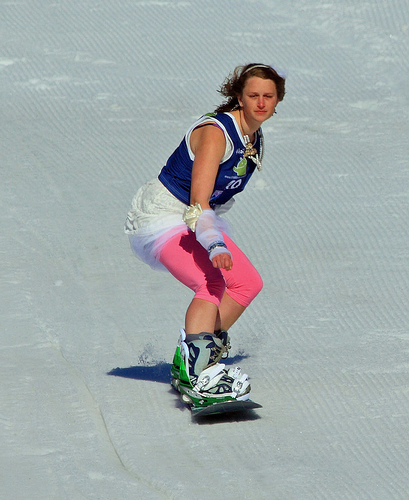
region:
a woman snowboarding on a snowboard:
[124, 61, 287, 416]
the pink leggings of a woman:
[156, 222, 263, 303]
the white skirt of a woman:
[127, 182, 235, 258]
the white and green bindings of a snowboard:
[175, 345, 248, 406]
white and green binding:
[172, 328, 198, 385]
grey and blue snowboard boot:
[187, 335, 249, 398]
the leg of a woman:
[152, 225, 219, 359]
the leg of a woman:
[195, 206, 258, 342]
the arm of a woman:
[190, 118, 222, 249]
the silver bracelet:
[207, 241, 225, 252]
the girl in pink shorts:
[87, 189, 278, 381]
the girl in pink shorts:
[100, 80, 348, 425]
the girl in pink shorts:
[116, 85, 250, 341]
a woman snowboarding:
[96, 69, 332, 433]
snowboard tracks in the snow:
[278, 343, 382, 499]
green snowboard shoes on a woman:
[166, 349, 229, 415]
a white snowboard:
[170, 376, 261, 432]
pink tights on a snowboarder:
[150, 225, 304, 341]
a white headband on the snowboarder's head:
[237, 65, 280, 80]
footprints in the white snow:
[277, 28, 394, 153]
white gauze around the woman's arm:
[189, 202, 228, 266]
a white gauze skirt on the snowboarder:
[117, 197, 215, 246]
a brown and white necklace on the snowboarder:
[233, 120, 268, 181]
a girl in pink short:
[82, 149, 323, 390]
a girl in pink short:
[98, 81, 245, 304]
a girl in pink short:
[141, 80, 330, 326]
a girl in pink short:
[152, 144, 285, 294]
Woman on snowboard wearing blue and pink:
[106, 43, 319, 439]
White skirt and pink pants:
[127, 182, 266, 339]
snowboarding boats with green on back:
[170, 331, 262, 419]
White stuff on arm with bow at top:
[174, 200, 236, 278]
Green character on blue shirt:
[231, 150, 250, 178]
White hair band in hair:
[236, 60, 272, 79]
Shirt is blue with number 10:
[160, 114, 273, 209]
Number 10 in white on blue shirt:
[222, 176, 243, 198]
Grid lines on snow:
[101, 125, 383, 366]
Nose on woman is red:
[256, 99, 271, 107]